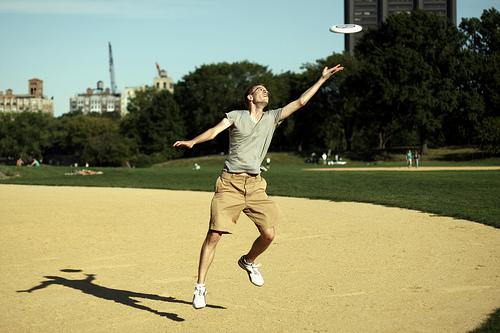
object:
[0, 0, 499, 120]
sky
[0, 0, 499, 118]
cloud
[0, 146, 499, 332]
ground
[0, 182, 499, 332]
sand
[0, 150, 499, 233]
grass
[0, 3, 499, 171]
trees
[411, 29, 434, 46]
leaves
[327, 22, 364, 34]
frisbee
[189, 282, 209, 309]
feet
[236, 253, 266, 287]
feet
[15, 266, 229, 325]
shadow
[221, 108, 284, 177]
shirt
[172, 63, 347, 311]
man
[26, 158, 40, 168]
people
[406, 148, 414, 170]
people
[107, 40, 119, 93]
cranes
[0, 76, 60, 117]
buildings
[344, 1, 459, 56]
building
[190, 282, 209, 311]
shoes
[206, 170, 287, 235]
shorts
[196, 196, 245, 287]
leg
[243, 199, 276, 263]
leg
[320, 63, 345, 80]
hand